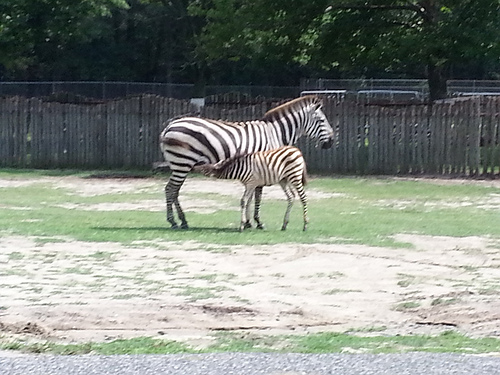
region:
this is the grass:
[86, 215, 121, 230]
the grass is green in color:
[81, 215, 122, 236]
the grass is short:
[111, 218, 141, 233]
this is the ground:
[253, 252, 284, 287]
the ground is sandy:
[269, 271, 299, 294]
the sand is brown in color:
[298, 270, 335, 297]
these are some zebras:
[153, 82, 336, 226]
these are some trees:
[73, 3, 400, 95]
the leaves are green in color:
[218, 10, 246, 37]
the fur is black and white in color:
[188, 128, 240, 148]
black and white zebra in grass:
[134, 68, 365, 150]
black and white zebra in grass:
[221, 148, 313, 222]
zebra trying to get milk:
[200, 155, 320, 214]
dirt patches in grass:
[146, 253, 441, 354]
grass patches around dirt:
[167, 199, 322, 244]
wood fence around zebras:
[18, 95, 495, 193]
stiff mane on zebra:
[268, 97, 309, 123]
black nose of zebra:
[324, 119, 341, 160]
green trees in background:
[43, 13, 490, 114]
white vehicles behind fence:
[288, 73, 468, 117]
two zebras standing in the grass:
[137, 86, 347, 243]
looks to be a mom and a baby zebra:
[111, 88, 346, 241]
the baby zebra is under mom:
[190, 135, 332, 242]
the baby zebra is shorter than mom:
[191, 133, 332, 245]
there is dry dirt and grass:
[2, 182, 172, 349]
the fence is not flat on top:
[10, 89, 296, 119]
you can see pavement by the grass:
[17, 339, 497, 373]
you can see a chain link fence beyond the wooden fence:
[5, 75, 316, 100]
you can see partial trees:
[5, 46, 495, 89]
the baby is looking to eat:
[161, 137, 332, 242]